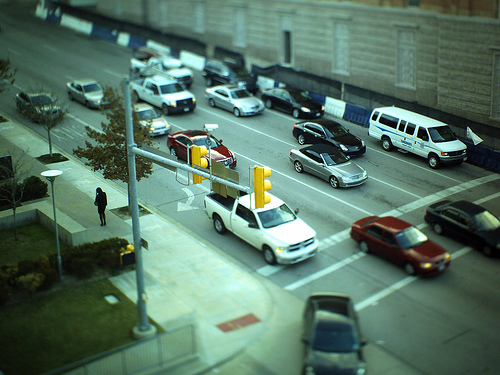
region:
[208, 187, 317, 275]
white truck is stopped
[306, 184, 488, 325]
white crosswalk on road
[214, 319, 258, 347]
red curb on sidewalk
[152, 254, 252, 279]
sidewalk is light grey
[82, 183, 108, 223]
person standing on sidewalk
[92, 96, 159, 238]
green tree next to road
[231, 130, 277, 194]
road is dark grey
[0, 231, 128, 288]
small bushes next to sidewalk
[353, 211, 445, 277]
the car is red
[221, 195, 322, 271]
the car is white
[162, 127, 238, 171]
the car is red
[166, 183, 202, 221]
the sign says leftturn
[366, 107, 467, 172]
the van is white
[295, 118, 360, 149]
the car is black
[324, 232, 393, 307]
the lines re white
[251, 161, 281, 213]
the traffic light is yellow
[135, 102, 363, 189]
the road is four lanes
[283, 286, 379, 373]
car in mid turn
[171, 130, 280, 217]
two traffic lights on a pole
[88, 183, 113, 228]
person walking along the sidewalk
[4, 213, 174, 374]
green grass on the ground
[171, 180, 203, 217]
white arrow on the road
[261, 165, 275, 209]
yellow cones around the lights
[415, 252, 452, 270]
two lights on the front of the vehicle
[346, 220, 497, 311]
white line painted on the ground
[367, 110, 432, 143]
windows on the side of the vehicle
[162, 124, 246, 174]
red car on the road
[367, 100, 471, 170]
large white transportation van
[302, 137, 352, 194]
a vehicle on the road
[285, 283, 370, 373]
a vehicle on the road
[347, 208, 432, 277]
a vehicle on the road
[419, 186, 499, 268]
a vehicle on the road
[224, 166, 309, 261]
a vehicle on the road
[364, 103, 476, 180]
a vehicle on the road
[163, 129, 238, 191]
a vehicle on the road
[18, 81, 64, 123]
a vehicle on the road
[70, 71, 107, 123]
a vehicle on the road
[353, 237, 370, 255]
Tire of a car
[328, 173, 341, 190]
Tire of a car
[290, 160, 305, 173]
Tire of a car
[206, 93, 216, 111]
Tire of a car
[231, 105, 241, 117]
Tire of a car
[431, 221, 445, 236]
Tire of a car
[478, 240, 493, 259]
Tire of a car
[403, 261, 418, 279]
Tire of a car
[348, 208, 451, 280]
A car on a street.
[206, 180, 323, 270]
A car on a street.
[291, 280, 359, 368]
A car on a street.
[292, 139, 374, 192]
A car on a street.